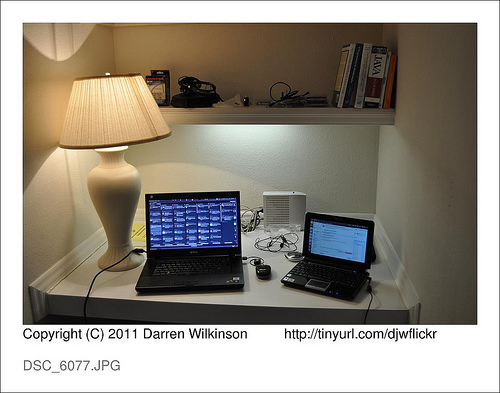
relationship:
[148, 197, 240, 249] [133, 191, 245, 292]
screen in front of laptop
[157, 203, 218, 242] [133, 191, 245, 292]
display of laptop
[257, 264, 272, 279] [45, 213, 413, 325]
mouse on top of desk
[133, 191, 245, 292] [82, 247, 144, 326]
laptop has cord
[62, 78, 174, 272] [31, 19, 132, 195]
lamp has shade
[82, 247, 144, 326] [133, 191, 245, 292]
cord going into laptop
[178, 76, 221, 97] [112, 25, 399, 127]
headphone bundled on shelf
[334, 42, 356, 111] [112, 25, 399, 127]
book ide of shelf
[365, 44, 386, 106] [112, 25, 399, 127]
book ide of shelf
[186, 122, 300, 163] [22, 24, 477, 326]
light reflecting on wall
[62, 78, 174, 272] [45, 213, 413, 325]
lamp on top of desk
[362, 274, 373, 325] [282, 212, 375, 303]
cord hanging off netbook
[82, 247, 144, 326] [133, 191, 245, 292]
cord hanging off laptop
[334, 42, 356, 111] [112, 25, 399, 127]
book on top of shelf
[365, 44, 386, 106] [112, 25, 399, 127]
book on top of shelf